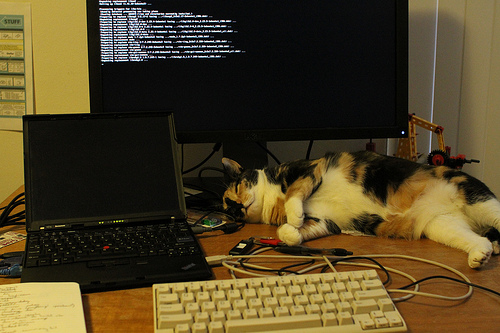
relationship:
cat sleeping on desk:
[217, 154, 498, 269] [2, 183, 495, 331]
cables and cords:
[204, 252, 498, 303] [2, 187, 28, 226]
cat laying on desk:
[217, 154, 498, 269] [2, 183, 495, 331]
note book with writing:
[0, 282, 87, 332] [2, 285, 66, 332]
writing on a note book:
[2, 285, 66, 332] [0, 282, 87, 332]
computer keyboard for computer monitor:
[154, 271, 404, 332] [86, 0, 410, 208]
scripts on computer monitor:
[98, 0, 245, 65] [86, 0, 410, 208]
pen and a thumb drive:
[274, 244, 353, 260] [230, 236, 254, 256]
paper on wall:
[0, 2, 35, 132] [2, 2, 388, 197]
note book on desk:
[0, 282, 87, 332] [2, 183, 495, 331]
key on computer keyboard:
[192, 322, 206, 332] [154, 271, 404, 332]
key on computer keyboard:
[322, 312, 338, 325] [154, 271, 404, 332]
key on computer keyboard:
[232, 298, 246, 308] [154, 271, 404, 332]